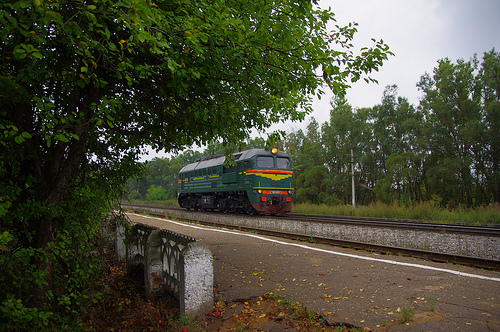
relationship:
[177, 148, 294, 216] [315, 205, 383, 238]
locomotive on tracks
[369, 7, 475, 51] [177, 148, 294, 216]
sky above locomotive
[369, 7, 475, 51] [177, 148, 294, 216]
sky by locomotive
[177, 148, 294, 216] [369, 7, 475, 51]
locomotive below sky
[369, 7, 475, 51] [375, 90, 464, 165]
sky above tree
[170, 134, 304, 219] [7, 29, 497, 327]
locomotive moving through countryside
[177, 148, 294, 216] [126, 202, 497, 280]
locomotive on track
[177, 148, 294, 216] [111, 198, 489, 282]
locomotive on track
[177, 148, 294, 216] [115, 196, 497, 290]
locomotive on tracks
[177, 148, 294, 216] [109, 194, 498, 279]
locomotive on tracks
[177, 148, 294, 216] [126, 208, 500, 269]
locomotive on track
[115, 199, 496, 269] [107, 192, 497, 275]
rocks in between railroad tracks